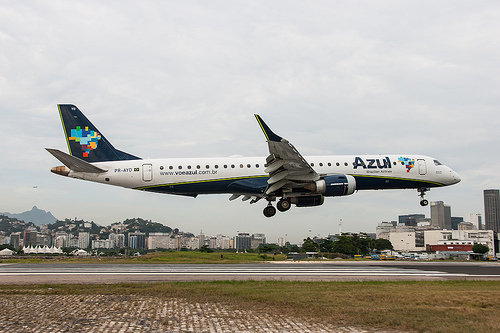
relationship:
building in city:
[234, 232, 266, 257] [1, 188, 498, 261]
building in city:
[386, 225, 496, 260] [1, 188, 498, 261]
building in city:
[125, 228, 147, 253] [1, 188, 498, 261]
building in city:
[426, 200, 455, 230] [1, 188, 498, 261]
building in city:
[481, 187, 498, 230] [1, 188, 498, 261]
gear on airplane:
[258, 191, 324, 214] [44, 99, 466, 219]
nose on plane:
[452, 172, 461, 184] [33, 82, 478, 234]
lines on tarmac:
[2, 270, 385, 275] [0, 255, 499, 286]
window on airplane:
[169, 165, 174, 169] [45, 100, 464, 216]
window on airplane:
[187, 165, 192, 170] [45, 100, 464, 216]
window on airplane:
[203, 155, 227, 174] [45, 94, 455, 200]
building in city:
[330, 137, 499, 306] [1, 187, 499, 261]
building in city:
[426, 200, 455, 234] [4, 214, 493, 266]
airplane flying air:
[45, 100, 464, 216] [147, 89, 430, 150]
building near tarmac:
[387, 218, 477, 268] [277, 256, 495, 301]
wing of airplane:
[251, 105, 323, 183] [39, 91, 467, 219]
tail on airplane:
[58, 104, 142, 162] [44, 99, 466, 219]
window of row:
[157, 163, 165, 170] [155, 160, 346, 169]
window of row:
[166, 163, 176, 170] [155, 160, 346, 169]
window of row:
[176, 163, 184, 170] [155, 160, 346, 169]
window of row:
[186, 162, 193, 169] [155, 160, 346, 169]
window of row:
[194, 162, 202, 171] [155, 160, 346, 169]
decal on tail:
[66, 124, 100, 157] [36, 98, 135, 183]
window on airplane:
[178, 165, 183, 169] [37, 92, 455, 209]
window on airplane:
[196, 165, 200, 170] [24, 92, 489, 213]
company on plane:
[347, 152, 403, 177] [99, 114, 499, 214]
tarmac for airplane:
[0, 247, 499, 294] [45, 100, 464, 216]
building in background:
[386, 225, 496, 260] [3, 178, 499, 263]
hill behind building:
[107, 217, 182, 231] [250, 233, 266, 251]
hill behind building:
[40, 216, 105, 237] [250, 233, 266, 251]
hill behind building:
[40, 216, 108, 233] [250, 233, 266, 251]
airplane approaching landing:
[44, 99, 466, 219] [1, 250, 496, 290]